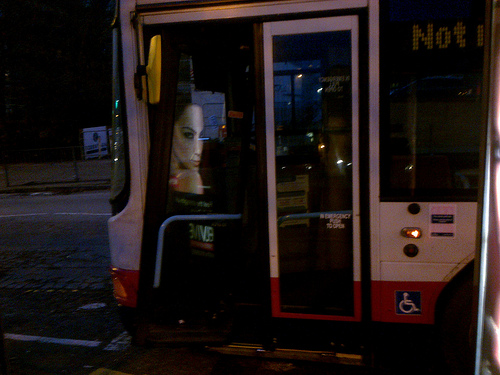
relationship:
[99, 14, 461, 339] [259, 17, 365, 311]
bus has door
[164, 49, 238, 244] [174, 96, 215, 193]
window has ad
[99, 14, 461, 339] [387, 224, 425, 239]
bus has light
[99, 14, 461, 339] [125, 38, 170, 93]
bus has mirror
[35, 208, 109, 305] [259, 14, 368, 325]
street has door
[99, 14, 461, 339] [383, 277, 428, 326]
bus has sign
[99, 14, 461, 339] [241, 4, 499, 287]
bus has side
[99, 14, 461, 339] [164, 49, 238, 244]
bus has window